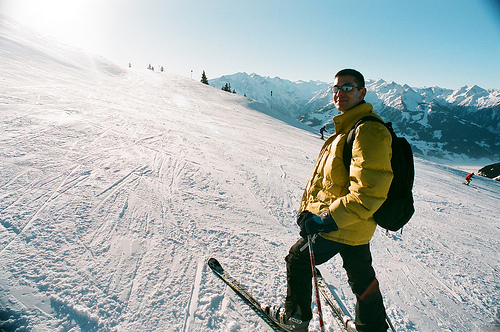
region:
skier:
[275, 55, 396, 329]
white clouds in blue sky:
[398, 26, 452, 57]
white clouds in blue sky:
[141, 9, 198, 37]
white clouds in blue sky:
[308, 21, 359, 53]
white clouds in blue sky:
[237, 15, 311, 56]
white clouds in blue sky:
[415, 41, 495, 89]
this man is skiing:
[182, 36, 439, 329]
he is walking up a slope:
[187, 33, 442, 329]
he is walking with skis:
[198, 23, 448, 329]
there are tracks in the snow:
[68, 107, 209, 324]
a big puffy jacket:
[295, 98, 424, 254]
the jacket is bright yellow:
[300, 108, 408, 246]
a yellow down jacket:
[295, 107, 406, 249]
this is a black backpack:
[352, 110, 430, 237]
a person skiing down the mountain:
[456, 160, 484, 199]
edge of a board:
[202, 254, 229, 297]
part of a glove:
[293, 225, 305, 240]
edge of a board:
[226, 279, 241, 304]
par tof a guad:
[276, 268, 291, 300]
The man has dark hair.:
[326, 61, 383, 83]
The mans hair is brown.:
[323, 63, 368, 88]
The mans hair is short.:
[332, 59, 362, 82]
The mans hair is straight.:
[331, 65, 366, 87]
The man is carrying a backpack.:
[348, 110, 433, 240]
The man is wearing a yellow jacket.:
[281, 95, 443, 218]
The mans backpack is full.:
[332, 111, 419, 234]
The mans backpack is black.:
[353, 112, 431, 240]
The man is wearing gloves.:
[291, 199, 341, 241]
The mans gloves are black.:
[285, 201, 379, 253]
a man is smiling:
[330, 69, 366, 109]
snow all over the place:
[0, 15, 498, 327]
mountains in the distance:
[204, 70, 499, 171]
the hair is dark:
[335, 68, 365, 90]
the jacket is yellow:
[301, 103, 393, 244]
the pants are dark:
[284, 232, 388, 327]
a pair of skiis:
[207, 258, 354, 330]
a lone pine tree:
[200, 70, 209, 83]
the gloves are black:
[300, 210, 335, 235]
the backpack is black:
[375, 136, 414, 230]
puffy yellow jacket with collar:
[280, 105, 395, 255]